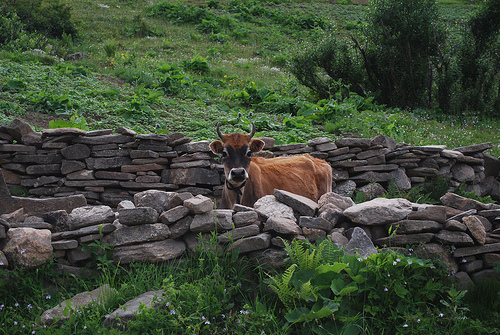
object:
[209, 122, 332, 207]
cow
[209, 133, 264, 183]
face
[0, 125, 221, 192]
wall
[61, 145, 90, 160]
rocks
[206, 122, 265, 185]
head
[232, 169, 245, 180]
nose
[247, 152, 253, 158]
eye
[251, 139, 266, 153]
ear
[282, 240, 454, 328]
shrub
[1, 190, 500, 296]
wall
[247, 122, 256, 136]
horns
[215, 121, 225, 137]
horns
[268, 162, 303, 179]
brown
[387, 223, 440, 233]
stone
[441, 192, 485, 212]
stone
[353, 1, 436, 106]
large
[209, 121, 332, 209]
body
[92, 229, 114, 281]
plant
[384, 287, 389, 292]
flower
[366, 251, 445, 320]
plant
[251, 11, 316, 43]
grass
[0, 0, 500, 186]
hill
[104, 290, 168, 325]
stones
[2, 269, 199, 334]
grass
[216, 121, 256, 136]
two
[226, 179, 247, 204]
rope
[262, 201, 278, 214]
bright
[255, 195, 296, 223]
rock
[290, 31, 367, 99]
trees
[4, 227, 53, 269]
stone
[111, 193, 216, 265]
stacked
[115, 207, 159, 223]
stones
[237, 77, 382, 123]
plants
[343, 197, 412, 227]
large